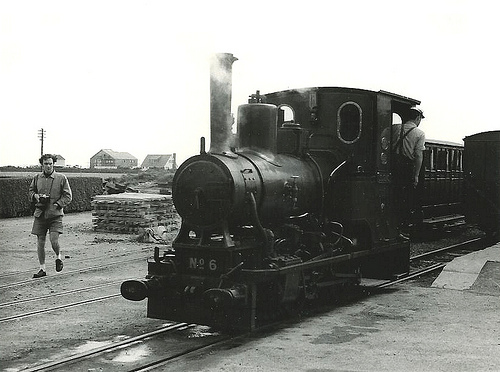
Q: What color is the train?
A: Black.